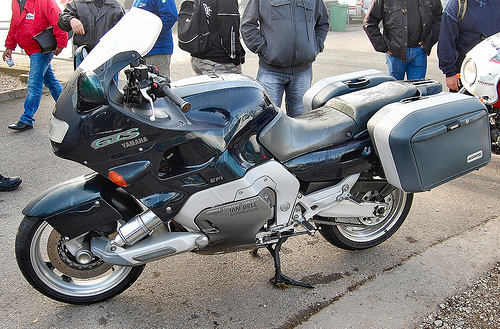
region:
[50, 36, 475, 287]
a motorcyle in the area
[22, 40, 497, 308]
the motorcycle is silver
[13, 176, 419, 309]
wheels on the motorcycle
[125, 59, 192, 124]
handles on the motorcycle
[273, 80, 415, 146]
the seat on the motorcycle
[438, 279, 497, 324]
rocks on the ground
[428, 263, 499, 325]
the rocks are small in size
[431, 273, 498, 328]
the rocks are gray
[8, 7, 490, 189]
people standing near the motorcycle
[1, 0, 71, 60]
a red jacket being worn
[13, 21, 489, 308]
one blue and black motorcycle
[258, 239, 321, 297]
one black metal motorcycle kickstand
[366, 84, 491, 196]
one gray storage motorcycle box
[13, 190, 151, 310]
one front black motorcycle tire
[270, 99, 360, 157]
one gray motorcycle seat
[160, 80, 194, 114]
one black motorcycle handlebar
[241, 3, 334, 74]
man wearing black leather jacket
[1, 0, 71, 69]
man wearing red jacket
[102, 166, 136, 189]
one front orange motorcycle light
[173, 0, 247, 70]
person with black backpack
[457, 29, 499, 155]
A Honda motorcycle.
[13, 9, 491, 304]
A Yamaha motorcycle.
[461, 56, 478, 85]
A headlight on a Honda motorcycle.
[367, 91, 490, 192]
The right pannier on a Yamaha motorcycle.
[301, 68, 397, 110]
The left pannier on a Yamaha motorcycle.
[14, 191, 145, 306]
The front wheel on a Yamaha motorcycle.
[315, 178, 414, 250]
The rear wheel on a Yamaha motorcycle.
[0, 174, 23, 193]
A black shoe.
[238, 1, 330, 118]
A person standing around.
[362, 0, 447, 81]
A person standing around.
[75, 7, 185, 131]
windshield on motorcycle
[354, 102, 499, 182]
bag on side of motorcycle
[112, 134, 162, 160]
YAMAHA written on side of motorcycle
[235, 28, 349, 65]
hands in their pockets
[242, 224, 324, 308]
kickstand on the motorcycle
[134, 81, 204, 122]
handle bar on the motorcycle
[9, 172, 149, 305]
wheel on the motorcycle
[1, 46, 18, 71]
man is carrying a can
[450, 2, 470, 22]
two yellow stripes on the jacket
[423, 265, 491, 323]
gravel next to the sidewalk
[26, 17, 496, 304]
a motorcycle sitting on the side of the road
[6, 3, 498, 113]
the people standing around the motorcycle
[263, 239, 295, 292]
the kickstand for the motorcycle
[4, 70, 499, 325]
the road the motorcycle is parked on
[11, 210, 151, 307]
the front wheel of the motorcyle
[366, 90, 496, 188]
a storage case on the side of the motorcycle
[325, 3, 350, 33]
a trash dumpster sitting on the road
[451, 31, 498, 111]
the front end of another motorcycle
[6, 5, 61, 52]
the red jacket a man is wearing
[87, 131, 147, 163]
some writing on the motorcycle